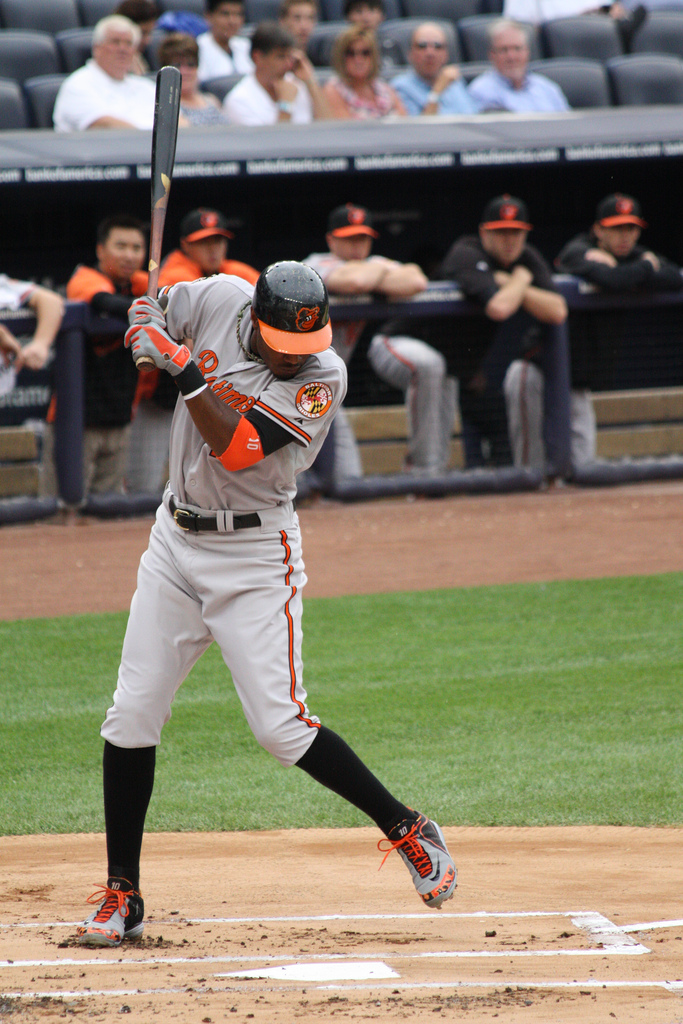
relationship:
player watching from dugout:
[59, 211, 160, 301] [0, 153, 679, 524]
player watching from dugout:
[153, 209, 259, 284] [0, 153, 679, 524]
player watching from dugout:
[301, 197, 451, 487] [0, 153, 679, 524]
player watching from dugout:
[446, 180, 575, 478] [0, 153, 679, 524]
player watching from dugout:
[550, 184, 674, 390] [0, 153, 679, 524]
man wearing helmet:
[77, 261, 458, 947] [251, 259, 334, 357]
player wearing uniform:
[367, 194, 569, 479] [444, 235, 580, 470]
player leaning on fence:
[367, 194, 569, 479] [3, 254, 682, 432]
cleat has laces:
[384, 803, 464, 912] [371, 818, 433, 878]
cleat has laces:
[68, 875, 147, 953] [87, 879, 139, 923]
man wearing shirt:
[390, 17, 480, 122] [389, 60, 478, 120]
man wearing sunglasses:
[390, 17, 480, 122] [409, 40, 447, 52]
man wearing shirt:
[46, 16, 186, 130] [46, 53, 177, 129]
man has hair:
[46, 16, 186, 130] [92, 9, 141, 49]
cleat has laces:
[76, 877, 144, 947] [87, 883, 133, 923]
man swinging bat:
[77, 261, 458, 947] [128, 61, 185, 368]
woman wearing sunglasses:
[319, 78, 395, 152] [342, 139, 365, 156]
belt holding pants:
[152, 481, 287, 549] [99, 483, 336, 756]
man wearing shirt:
[77, 261, 458, 947] [122, 273, 365, 554]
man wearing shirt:
[77, 261, 458, 947] [159, 259, 352, 537]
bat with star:
[124, 68, 212, 374] [140, 167, 177, 206]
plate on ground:
[194, 945, 407, 993] [10, 598, 676, 1010]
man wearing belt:
[80, 253, 457, 827] [150, 485, 265, 571]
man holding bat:
[77, 261, 458, 947] [119, 137, 187, 375]